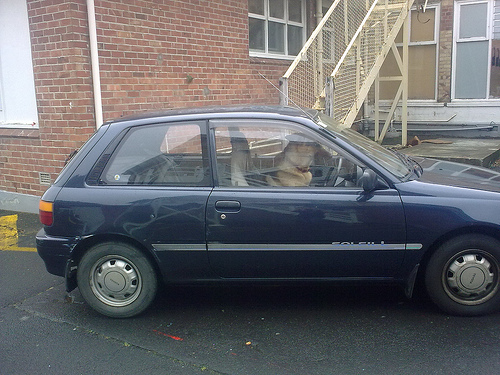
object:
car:
[30, 104, 499, 318]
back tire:
[74, 240, 156, 318]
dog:
[263, 134, 331, 187]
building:
[0, 0, 498, 219]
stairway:
[277, 3, 413, 149]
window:
[0, 0, 43, 130]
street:
[0, 207, 500, 373]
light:
[34, 200, 53, 211]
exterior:
[1, 0, 500, 200]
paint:
[0, 212, 38, 254]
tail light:
[38, 211, 53, 227]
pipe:
[80, 1, 106, 131]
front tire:
[421, 234, 498, 314]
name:
[331, 238, 387, 250]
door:
[201, 117, 408, 283]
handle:
[213, 198, 242, 213]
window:
[373, 43, 439, 102]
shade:
[405, 7, 435, 43]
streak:
[150, 327, 182, 342]